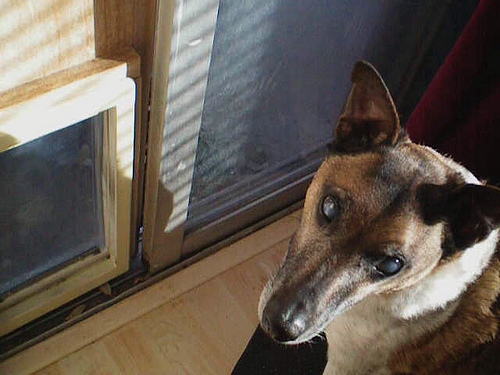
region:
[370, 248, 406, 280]
eye of the dog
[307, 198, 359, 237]
eye of the dog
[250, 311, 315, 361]
nose of the dog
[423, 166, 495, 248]
ear of the dog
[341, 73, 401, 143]
ear of the dog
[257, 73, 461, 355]
head of the dog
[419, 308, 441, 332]
fur of the dog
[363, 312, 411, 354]
fur of the dog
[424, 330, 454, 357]
fur of the dog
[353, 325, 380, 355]
fur of the dog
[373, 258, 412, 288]
eye of the dog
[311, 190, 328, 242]
eye of the dog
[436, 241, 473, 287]
fur of the dog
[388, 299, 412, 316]
fur of the dog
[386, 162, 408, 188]
fur of the dog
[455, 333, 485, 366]
fur of the dog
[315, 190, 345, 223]
eye of the brown dog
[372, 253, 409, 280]
eye of the brown dog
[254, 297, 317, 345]
nose of the brown dog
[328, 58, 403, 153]
ear of the brown dog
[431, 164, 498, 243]
ear of the brown dog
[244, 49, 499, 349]
head of the brown dog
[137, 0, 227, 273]
wooden board on the door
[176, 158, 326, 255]
wooden board on the door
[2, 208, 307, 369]
floor is made of wood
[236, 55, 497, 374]
brown dog looking at the camera